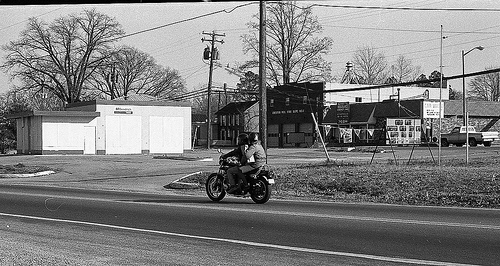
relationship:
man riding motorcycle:
[231, 126, 264, 190] [205, 153, 277, 198]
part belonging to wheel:
[257, 190, 267, 198] [248, 176, 273, 204]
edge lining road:
[173, 190, 484, 209] [0, 181, 480, 263]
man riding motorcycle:
[221, 133, 250, 192] [204, 143, 275, 203]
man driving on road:
[221, 133, 250, 192] [11, 144, 484, 195]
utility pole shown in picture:
[198, 26, 226, 149] [1, 1, 483, 261]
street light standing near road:
[460, 43, 485, 124] [11, 144, 484, 195]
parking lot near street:
[10, 136, 390, 193] [7, 190, 499, 259]